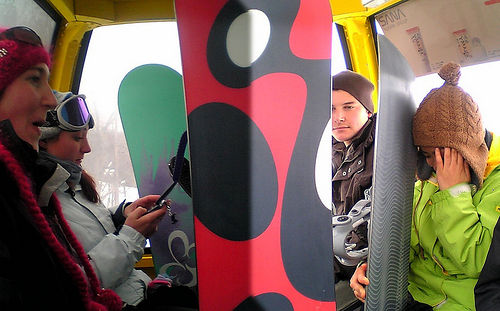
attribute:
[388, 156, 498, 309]
jacket — lime green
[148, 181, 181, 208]
cellular phone — slim 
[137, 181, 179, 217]
cell phone — her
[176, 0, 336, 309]
snowboard — red, black, white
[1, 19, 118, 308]
woman — black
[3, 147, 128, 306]
sweater — red 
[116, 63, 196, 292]
snowboard — teal, purple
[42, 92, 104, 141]
goggles — snow, pair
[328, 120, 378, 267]
jacket — black 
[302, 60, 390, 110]
beanie — black 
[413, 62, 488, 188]
hat — brown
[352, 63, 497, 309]
person — hiding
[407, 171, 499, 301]
green jacket — lime 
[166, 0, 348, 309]
snowboard — Red, white , navy , blue 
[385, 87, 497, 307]
person — knitted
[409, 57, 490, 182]
beany — brown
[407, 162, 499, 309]
jacket — green 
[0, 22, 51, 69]
cap — red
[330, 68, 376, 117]
knitted cap — brown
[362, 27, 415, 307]
snowboard — silver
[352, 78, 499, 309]
snowboarder — group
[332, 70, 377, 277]
snowboarder — group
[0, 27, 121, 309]
snowboarder — group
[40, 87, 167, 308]
snowboarder — group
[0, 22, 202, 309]
woman — sitting together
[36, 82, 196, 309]
woman — sitting together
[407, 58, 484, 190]
ski cap — Brown 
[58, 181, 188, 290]
jacket — white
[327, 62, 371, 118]
cap — black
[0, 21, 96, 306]
female — snowboarder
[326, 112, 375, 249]
jacket — brown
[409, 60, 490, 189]
cap — beige